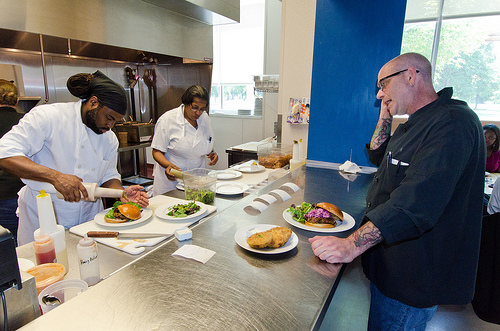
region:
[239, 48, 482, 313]
The man waits for his food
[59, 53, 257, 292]
food is prepared in front of customers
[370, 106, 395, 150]
tattoo on his right arm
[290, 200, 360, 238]
Burger on the plate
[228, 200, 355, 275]
The plates are round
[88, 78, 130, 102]
his hat is black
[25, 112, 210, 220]
their uniforms are white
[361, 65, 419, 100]
his glasses are black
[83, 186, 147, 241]
he is preparing a burger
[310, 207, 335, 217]
the onions are purple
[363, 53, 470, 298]
man wearing glasses and a black shirt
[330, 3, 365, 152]
blue wall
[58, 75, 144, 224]
man preparing a meal at a restaurant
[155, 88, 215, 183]
woman wearing white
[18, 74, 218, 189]
two people working in a restaurant kitchen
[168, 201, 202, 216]
plate of lettuce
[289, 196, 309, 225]
lettuce on the side of a dish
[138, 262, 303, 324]
silver countertop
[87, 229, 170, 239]
knife with a brown handle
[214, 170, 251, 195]
two empty plates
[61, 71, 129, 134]
The man is wearing a black scarf.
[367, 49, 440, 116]
The man is bald.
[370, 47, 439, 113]
The man is wearing glasses.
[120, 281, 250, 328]
The counter is silver.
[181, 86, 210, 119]
The woman is wearing glasses.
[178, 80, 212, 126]
The woman is wearing a hair net.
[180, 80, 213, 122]
The womans hair is black.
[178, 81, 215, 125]
The woman's hair is short.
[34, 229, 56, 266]
The liquid in the bottle is red.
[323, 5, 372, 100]
The wall in the background is blue.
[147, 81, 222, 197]
Female cook behind the counter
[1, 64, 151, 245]
Male cook working behind the counter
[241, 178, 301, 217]
Four order tickets on the counter together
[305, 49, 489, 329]
Man in front of the counter getting food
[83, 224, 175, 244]
Large knife next to the cook preparing a meal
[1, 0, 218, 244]
Cooking area behind the cooks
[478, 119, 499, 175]
Woman sitting behind the man getting food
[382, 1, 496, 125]
Large window behind the man getting food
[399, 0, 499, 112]
Trees outside the window behind the man getting food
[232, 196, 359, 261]
Two plates in front of the man getting food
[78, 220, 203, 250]
knife with wooden handle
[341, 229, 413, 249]
tatoo on man's lower arm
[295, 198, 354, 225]
burger on white plate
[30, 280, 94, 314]
clear plastic bowl with spoons in it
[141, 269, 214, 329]
stainless steel counter top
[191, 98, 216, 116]
glasses on woman's face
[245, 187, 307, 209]
white paper with orders written on it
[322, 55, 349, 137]
blue wall at end of counter top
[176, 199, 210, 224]
green salad on white plate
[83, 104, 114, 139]
dark beard on man's face